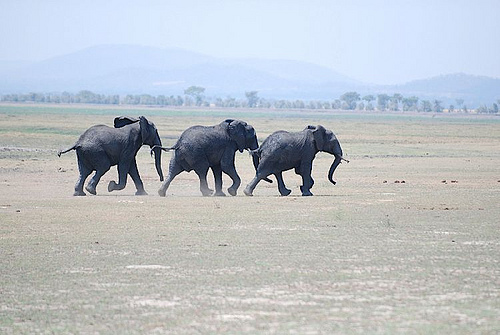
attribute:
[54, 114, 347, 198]
elephants — running, together, grey, moving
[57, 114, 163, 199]
elephant — gray, running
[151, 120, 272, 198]
elephant — gray, running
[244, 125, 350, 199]
elephant — gray, running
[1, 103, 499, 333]
grass — short, yellow, brown, green